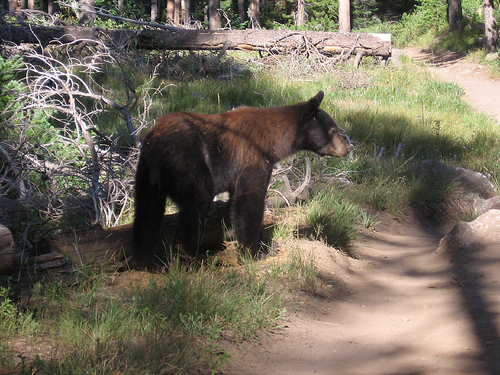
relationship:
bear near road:
[128, 87, 357, 261] [424, 52, 500, 118]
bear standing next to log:
[128, 87, 357, 261] [56, 219, 133, 269]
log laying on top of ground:
[56, 219, 133, 269] [107, 285, 215, 339]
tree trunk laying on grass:
[141, 22, 393, 61] [236, 62, 290, 87]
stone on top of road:
[434, 209, 499, 258] [424, 52, 500, 118]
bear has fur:
[128, 87, 357, 261] [235, 108, 282, 121]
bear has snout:
[128, 87, 357, 261] [347, 142, 355, 152]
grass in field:
[236, 62, 290, 87] [33, 52, 455, 129]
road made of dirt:
[424, 52, 500, 118] [423, 51, 467, 82]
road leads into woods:
[424, 52, 500, 118] [179, 0, 375, 27]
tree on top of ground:
[221, 29, 373, 59] [244, 57, 320, 80]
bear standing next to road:
[128, 87, 357, 261] [424, 52, 500, 118]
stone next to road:
[434, 209, 499, 258] [424, 52, 500, 118]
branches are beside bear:
[51, 58, 142, 113] [128, 87, 357, 261]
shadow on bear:
[192, 115, 282, 165] [128, 87, 357, 261]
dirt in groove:
[415, 223, 442, 238] [400, 211, 469, 234]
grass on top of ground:
[236, 62, 290, 87] [107, 285, 215, 339]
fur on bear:
[235, 108, 282, 121] [128, 87, 357, 261]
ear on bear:
[306, 92, 326, 112] [128, 87, 357, 261]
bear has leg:
[128, 87, 357, 261] [234, 164, 270, 246]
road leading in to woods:
[424, 52, 500, 118] [179, 0, 375, 27]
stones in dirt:
[326, 272, 347, 292] [339, 296, 373, 326]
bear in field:
[128, 87, 357, 261] [33, 52, 455, 129]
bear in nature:
[128, 87, 357, 261] [10, 3, 499, 89]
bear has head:
[128, 87, 357, 261] [304, 87, 356, 159]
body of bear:
[149, 106, 277, 183] [128, 87, 357, 261]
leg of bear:
[234, 164, 270, 246] [128, 87, 357, 261]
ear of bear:
[306, 92, 326, 112] [128, 87, 357, 261]